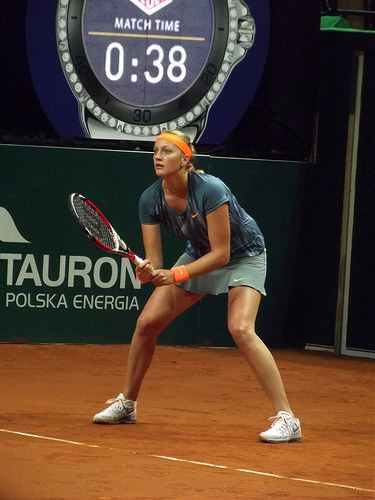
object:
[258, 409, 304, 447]
sneakers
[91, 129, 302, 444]
woman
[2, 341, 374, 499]
ground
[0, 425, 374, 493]
line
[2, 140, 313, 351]
barrier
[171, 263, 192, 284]
band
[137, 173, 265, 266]
shirt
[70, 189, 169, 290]
bat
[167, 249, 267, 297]
skirt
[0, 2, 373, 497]
tennis court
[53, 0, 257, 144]
bilboard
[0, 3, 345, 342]
wall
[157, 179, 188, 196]
chain